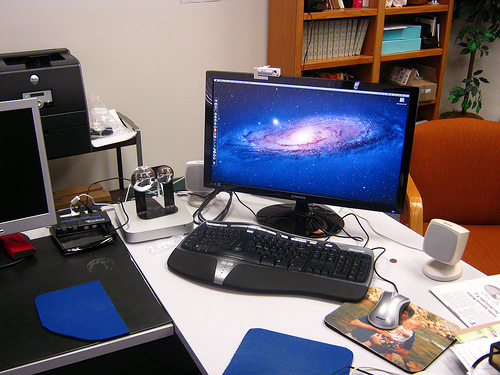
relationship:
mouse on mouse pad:
[363, 290, 412, 332] [324, 287, 462, 375]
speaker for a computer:
[421, 214, 470, 282] [201, 65, 422, 237]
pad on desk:
[36, 284, 150, 356] [18, 221, 226, 373]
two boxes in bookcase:
[383, 26, 421, 53] [272, 2, 453, 129]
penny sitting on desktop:
[392, 256, 398, 265] [102, 190, 496, 373]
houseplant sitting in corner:
[439, 0, 499, 122] [447, 15, 490, 123]